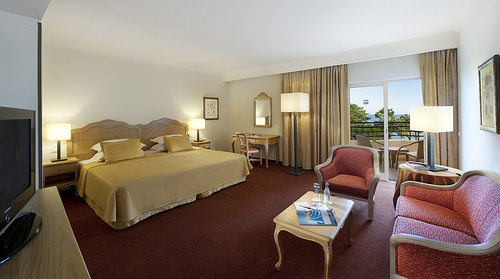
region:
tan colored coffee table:
[274, 178, 349, 276]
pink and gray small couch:
[404, 169, 454, 276]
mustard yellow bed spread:
[68, 118, 287, 222]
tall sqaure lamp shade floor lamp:
[269, 83, 322, 179]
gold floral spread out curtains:
[280, 58, 497, 194]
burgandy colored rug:
[182, 224, 265, 270]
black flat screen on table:
[1, 104, 72, 229]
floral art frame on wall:
[187, 94, 227, 126]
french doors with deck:
[364, 104, 419, 162]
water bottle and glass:
[313, 176, 350, 212]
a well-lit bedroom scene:
[6, 3, 490, 278]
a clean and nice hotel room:
[6, 5, 494, 274]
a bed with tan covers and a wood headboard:
[71, 120, 248, 229]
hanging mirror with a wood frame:
[248, 92, 275, 130]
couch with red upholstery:
[388, 168, 498, 276]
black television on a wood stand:
[1, 104, 41, 269]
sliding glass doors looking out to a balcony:
[348, 83, 421, 175]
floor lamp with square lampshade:
[277, 91, 310, 178]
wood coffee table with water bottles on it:
[271, 188, 357, 275]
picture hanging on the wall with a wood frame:
[200, 92, 220, 120]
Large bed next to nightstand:
[70, 112, 252, 231]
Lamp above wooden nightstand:
[45, 114, 73, 164]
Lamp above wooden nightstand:
[190, 113, 207, 143]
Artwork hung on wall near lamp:
[200, 94, 222, 121]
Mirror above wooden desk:
[250, 88, 275, 129]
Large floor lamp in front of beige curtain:
[277, 88, 312, 180]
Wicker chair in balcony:
[394, 136, 427, 172]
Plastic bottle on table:
[324, 180, 334, 201]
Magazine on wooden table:
[290, 195, 337, 232]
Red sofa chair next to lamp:
[312, 141, 383, 221]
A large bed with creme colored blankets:
[67, 117, 252, 230]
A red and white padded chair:
[312, 144, 381, 222]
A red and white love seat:
[387, 170, 498, 277]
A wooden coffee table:
[271, 189, 356, 278]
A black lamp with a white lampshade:
[407, 102, 454, 172]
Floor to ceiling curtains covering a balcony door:
[279, 49, 459, 171]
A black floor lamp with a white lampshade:
[279, 90, 311, 177]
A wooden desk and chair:
[228, 131, 279, 168]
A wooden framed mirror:
[252, 89, 273, 127]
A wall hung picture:
[202, 95, 219, 120]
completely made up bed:
[59, 105, 255, 230]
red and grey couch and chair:
[315, 138, 498, 277]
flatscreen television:
[2, 103, 39, 249]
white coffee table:
[275, 175, 358, 270]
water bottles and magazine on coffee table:
[290, 175, 344, 231]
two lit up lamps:
[271, 88, 462, 176]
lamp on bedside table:
[40, 120, 76, 166]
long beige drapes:
[279, 55, 462, 170]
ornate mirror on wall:
[247, 88, 280, 133]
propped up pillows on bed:
[86, 127, 199, 163]